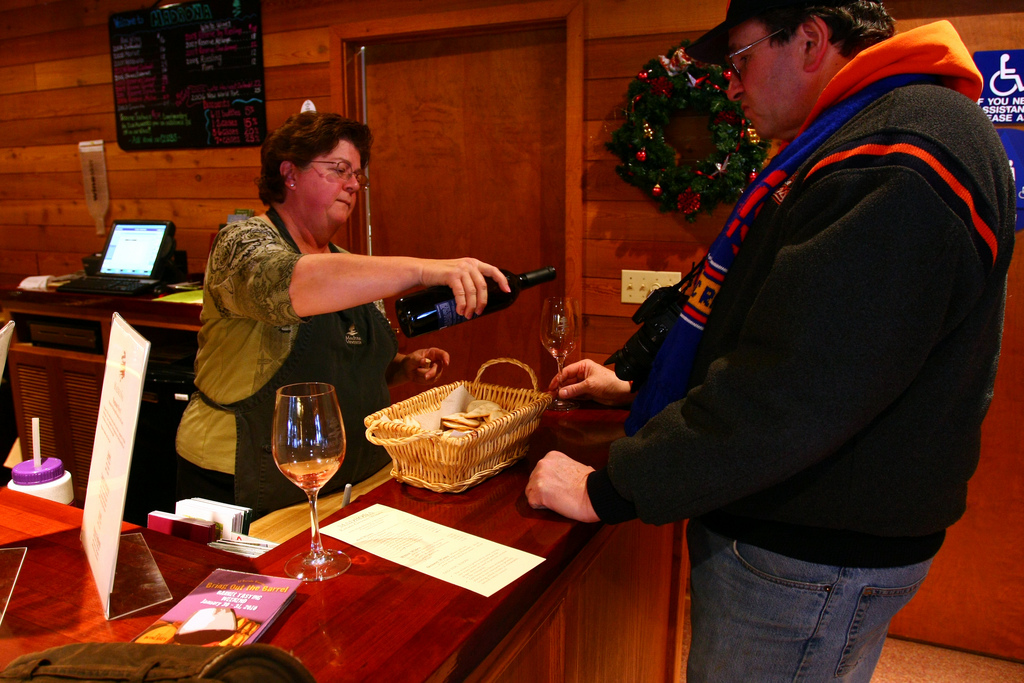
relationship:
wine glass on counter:
[266, 376, 349, 582] [7, 368, 619, 660]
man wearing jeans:
[544, 0, 1016, 680] [669, 533, 932, 673]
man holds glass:
[544, 0, 1016, 680] [522, 294, 581, 408]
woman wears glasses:
[169, 115, 523, 480] [321, 151, 360, 190]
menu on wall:
[106, 0, 267, 153] [119, 155, 238, 210]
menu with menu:
[106, 0, 267, 153] [115, 22, 256, 133]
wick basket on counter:
[363, 354, 551, 492] [2, 444, 597, 679]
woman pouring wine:
[175, 113, 511, 512] [544, 264, 576, 318]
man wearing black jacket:
[544, 0, 1016, 680] [779, 246, 963, 417]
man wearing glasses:
[544, 0, 1016, 680] [690, 35, 755, 83]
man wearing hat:
[544, 0, 1016, 680] [675, 1, 883, 86]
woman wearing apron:
[175, 113, 511, 512] [187, 209, 409, 507]